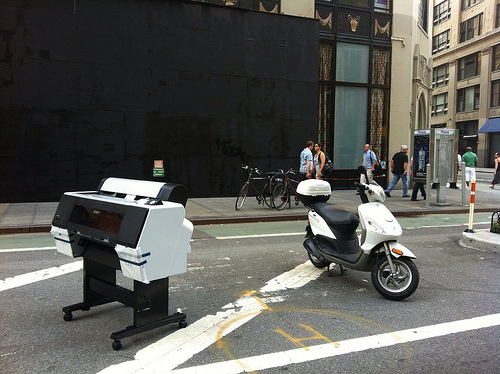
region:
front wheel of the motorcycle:
[373, 260, 416, 295]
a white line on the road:
[359, 310, 436, 352]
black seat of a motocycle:
[323, 195, 346, 235]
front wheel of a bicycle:
[231, 185, 251, 205]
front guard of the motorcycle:
[386, 240, 412, 258]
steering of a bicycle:
[237, 155, 266, 178]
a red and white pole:
[464, 180, 481, 238]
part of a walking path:
[202, 195, 239, 212]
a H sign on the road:
[256, 306, 345, 342]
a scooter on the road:
[274, 142, 422, 309]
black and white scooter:
[294, 176, 421, 289]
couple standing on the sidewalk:
[296, 136, 328, 189]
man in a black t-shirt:
[387, 138, 414, 202]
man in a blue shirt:
[355, 140, 382, 185]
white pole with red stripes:
[461, 166, 486, 228]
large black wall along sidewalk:
[12, 10, 322, 192]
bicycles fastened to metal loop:
[236, 161, 309, 213]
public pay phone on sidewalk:
[410, 125, 462, 208]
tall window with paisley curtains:
[316, 7, 399, 170]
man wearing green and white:
[457, 141, 482, 185]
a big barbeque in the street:
[46, 169, 188, 351]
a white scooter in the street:
[291, 175, 418, 299]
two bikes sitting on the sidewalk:
[237, 158, 293, 212]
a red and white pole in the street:
[465, 177, 476, 234]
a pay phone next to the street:
[431, 127, 456, 199]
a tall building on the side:
[426, 2, 499, 187]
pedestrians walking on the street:
[294, 139, 495, 206]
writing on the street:
[213, 285, 393, 370]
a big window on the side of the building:
[316, 37, 394, 174]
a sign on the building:
[146, 156, 161, 174]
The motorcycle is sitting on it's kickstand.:
[280, 170, 421, 312]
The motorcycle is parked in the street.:
[288, 175, 425, 298]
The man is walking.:
[388, 138, 411, 197]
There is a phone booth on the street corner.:
[410, 121, 464, 207]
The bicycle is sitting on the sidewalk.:
[231, 157, 296, 210]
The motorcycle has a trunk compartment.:
[292, 175, 337, 211]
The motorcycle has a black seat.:
[312, 200, 361, 230]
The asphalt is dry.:
[0, 222, 499, 372]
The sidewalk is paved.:
[2, 184, 467, 230]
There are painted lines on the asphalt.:
[0, 222, 499, 371]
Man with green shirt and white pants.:
[461, 143, 486, 190]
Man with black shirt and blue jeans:
[385, 140, 412, 197]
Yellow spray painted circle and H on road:
[211, 294, 449, 369]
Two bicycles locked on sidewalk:
[235, 155, 297, 211]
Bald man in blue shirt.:
[358, 138, 383, 182]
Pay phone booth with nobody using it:
[413, 125, 460, 205]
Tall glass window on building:
[333, 34, 371, 174]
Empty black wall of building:
[0, 19, 319, 136]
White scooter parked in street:
[298, 175, 434, 306]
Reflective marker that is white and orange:
[459, 180, 478, 242]